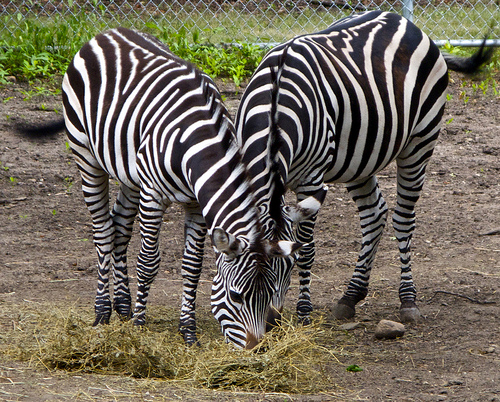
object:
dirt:
[5, 59, 496, 397]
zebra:
[232, 8, 449, 322]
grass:
[0, 6, 499, 67]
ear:
[209, 226, 239, 254]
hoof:
[332, 298, 356, 319]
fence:
[1, 1, 497, 62]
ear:
[283, 196, 321, 221]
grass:
[0, 298, 356, 394]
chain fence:
[0, 1, 494, 42]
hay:
[27, 297, 349, 389]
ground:
[2, 39, 497, 399]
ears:
[265, 239, 303, 259]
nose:
[243, 335, 271, 354]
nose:
[266, 310, 282, 333]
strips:
[349, 54, 399, 129]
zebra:
[60, 22, 317, 354]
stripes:
[181, 123, 196, 136]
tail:
[9, 112, 64, 142]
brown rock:
[375, 319, 407, 340]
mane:
[265, 122, 281, 221]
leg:
[133, 180, 163, 325]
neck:
[170, 105, 296, 255]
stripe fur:
[312, 37, 420, 141]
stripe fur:
[80, 61, 156, 147]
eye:
[226, 288, 246, 307]